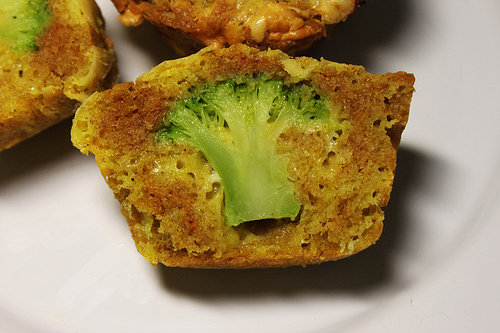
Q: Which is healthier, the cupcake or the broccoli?
A: The broccoli is healthier than the cupcake.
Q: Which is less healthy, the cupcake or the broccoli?
A: The cupcake is less healthy than the broccoli.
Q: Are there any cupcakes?
A: Yes, there is a cupcake.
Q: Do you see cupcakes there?
A: Yes, there is a cupcake.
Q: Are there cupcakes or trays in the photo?
A: Yes, there is a cupcake.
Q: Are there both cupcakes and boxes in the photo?
A: No, there is a cupcake but no boxes.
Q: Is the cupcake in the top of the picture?
A: Yes, the cupcake is in the top of the image.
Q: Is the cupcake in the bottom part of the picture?
A: No, the cupcake is in the top of the image.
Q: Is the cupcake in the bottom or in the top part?
A: The cupcake is in the top of the image.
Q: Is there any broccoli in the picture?
A: Yes, there is broccoli.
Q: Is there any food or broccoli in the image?
A: Yes, there is broccoli.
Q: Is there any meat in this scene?
A: No, there is no meat.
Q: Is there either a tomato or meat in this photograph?
A: No, there are no meat or tomatoes.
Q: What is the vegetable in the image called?
A: The vegetable is broccoli.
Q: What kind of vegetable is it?
A: The vegetable is broccoli.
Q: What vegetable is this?
A: That is broccoli.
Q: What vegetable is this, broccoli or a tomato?
A: That is broccoli.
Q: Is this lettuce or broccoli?
A: This is broccoli.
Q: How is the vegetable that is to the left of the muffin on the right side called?
A: The vegetable is broccoli.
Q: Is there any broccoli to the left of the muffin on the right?
A: Yes, there is broccoli to the left of the muffin.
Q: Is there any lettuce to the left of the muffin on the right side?
A: No, there is broccoli to the left of the muffin.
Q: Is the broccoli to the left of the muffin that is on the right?
A: Yes, the broccoli is to the left of the muffin.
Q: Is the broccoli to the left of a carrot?
A: No, the broccoli is to the left of the muffin.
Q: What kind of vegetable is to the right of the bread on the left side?
A: The vegetable is broccoli.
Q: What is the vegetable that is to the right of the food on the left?
A: The vegetable is broccoli.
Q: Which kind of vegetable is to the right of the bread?
A: The vegetable is broccoli.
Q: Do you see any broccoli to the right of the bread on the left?
A: Yes, there is broccoli to the right of the bread.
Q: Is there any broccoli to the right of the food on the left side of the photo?
A: Yes, there is broccoli to the right of the bread.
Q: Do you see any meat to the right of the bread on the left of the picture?
A: No, there is broccoli to the right of the bread.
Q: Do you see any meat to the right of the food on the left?
A: No, there is broccoli to the right of the bread.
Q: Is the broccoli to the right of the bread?
A: Yes, the broccoli is to the right of the bread.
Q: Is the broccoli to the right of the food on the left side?
A: Yes, the broccoli is to the right of the bread.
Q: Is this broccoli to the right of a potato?
A: No, the broccoli is to the right of the bread.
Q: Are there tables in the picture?
A: Yes, there is a table.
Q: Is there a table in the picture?
A: Yes, there is a table.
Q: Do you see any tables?
A: Yes, there is a table.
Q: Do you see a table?
A: Yes, there is a table.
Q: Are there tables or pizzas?
A: Yes, there is a table.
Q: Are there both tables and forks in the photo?
A: No, there is a table but no forks.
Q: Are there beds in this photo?
A: No, there are no beds.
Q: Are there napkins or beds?
A: No, there are no beds or napkins.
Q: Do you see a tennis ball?
A: No, there are no tennis balls.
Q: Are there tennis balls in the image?
A: No, there are no tennis balls.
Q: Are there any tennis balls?
A: No, there are no tennis balls.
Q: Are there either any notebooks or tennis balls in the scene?
A: No, there are no tennis balls or notebooks.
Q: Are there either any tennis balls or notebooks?
A: No, there are no tennis balls or notebooks.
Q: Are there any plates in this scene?
A: Yes, there is a plate.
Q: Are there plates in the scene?
A: Yes, there is a plate.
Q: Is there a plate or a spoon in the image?
A: Yes, there is a plate.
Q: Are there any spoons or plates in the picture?
A: Yes, there is a plate.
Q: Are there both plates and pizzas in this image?
A: No, there is a plate but no pizzas.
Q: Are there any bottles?
A: No, there are no bottles.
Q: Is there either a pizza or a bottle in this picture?
A: No, there are no bottles or pizzas.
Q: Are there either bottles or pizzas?
A: No, there are no bottles or pizzas.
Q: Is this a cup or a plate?
A: This is a plate.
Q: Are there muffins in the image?
A: Yes, there is a muffin.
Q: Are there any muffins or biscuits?
A: Yes, there is a muffin.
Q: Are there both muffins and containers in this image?
A: No, there is a muffin but no containers.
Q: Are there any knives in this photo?
A: No, there are no knives.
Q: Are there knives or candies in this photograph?
A: No, there are no knives or candies.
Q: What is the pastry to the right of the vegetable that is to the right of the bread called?
A: The pastry is a muffin.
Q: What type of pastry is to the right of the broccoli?
A: The pastry is a muffin.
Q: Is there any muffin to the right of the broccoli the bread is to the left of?
A: Yes, there is a muffin to the right of the broccoli.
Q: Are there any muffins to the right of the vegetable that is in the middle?
A: Yes, there is a muffin to the right of the broccoli.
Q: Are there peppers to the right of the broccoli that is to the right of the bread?
A: No, there is a muffin to the right of the broccoli.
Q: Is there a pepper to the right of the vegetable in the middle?
A: No, there is a muffin to the right of the broccoli.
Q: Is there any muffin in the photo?
A: Yes, there is a muffin.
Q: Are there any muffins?
A: Yes, there is a muffin.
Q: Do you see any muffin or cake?
A: Yes, there is a muffin.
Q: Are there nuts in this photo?
A: No, there are no nuts.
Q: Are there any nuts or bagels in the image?
A: No, there are no nuts or bagels.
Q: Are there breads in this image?
A: Yes, there is a bread.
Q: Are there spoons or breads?
A: Yes, there is a bread.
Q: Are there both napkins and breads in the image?
A: No, there is a bread but no napkins.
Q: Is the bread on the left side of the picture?
A: Yes, the bread is on the left of the image.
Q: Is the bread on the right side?
A: No, the bread is on the left of the image.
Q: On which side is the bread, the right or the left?
A: The bread is on the left of the image.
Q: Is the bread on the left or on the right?
A: The bread is on the left of the image.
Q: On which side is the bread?
A: The bread is on the left of the image.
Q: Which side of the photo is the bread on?
A: The bread is on the left of the image.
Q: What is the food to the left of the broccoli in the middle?
A: The food is a bread.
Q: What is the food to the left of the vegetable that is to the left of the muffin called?
A: The food is a bread.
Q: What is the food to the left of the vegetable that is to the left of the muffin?
A: The food is a bread.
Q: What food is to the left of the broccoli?
A: The food is a bread.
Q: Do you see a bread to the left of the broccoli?
A: Yes, there is a bread to the left of the broccoli.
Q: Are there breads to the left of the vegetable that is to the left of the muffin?
A: Yes, there is a bread to the left of the broccoli.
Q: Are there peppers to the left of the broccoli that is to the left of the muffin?
A: No, there is a bread to the left of the broccoli.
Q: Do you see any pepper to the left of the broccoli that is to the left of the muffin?
A: No, there is a bread to the left of the broccoli.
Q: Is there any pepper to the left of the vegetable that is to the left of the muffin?
A: No, there is a bread to the left of the broccoli.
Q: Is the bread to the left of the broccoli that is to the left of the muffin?
A: Yes, the bread is to the left of the broccoli.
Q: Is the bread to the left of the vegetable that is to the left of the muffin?
A: Yes, the bread is to the left of the broccoli.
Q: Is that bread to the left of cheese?
A: No, the bread is to the left of the broccoli.